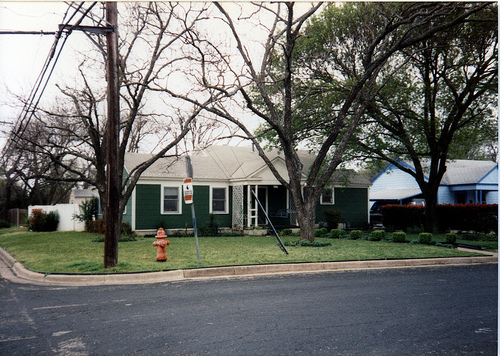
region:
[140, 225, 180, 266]
red fire hydrant on grass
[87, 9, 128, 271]
brown tree trunk on grass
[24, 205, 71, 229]
shrubs in side yard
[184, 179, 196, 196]
white sign on a pole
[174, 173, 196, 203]
white and red sign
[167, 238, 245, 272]
green grass in front lawn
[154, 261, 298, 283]
white curb by street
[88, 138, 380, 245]
A house in the foreground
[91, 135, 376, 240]
The house is green in color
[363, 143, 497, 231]
A white house on the right side of the image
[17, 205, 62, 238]
A bush in the background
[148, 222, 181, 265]
A fire hydrant in the foreground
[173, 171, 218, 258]
A street sign in the foreground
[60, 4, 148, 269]
A wooden pole in the foreground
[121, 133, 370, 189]
The roof of the house is light gray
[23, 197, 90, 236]
A white fence in the background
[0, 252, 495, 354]
A concrete street in the foreground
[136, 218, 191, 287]
this is a fire hydrant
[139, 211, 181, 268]
the hydrant is on the grass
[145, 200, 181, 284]
the hydrant is on the lawn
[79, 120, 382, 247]
this is a green house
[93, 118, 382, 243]
a green one-story house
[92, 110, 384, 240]
a detached single family home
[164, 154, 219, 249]
this is a street sign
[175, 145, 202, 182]
this is the back of a stop sign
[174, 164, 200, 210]
this is a neighborhood watch sign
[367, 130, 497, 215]
this is a blue house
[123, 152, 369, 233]
dark green ranch home with white trim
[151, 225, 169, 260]
a red fire hydrant by the road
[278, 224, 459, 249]
small bushes line the front walk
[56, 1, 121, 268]
a utility pole supports utility lines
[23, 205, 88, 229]
a white privacy fence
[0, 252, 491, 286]
a concrete curb along the road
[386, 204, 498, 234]
bushes that have turned red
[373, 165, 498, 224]
a white neighboring house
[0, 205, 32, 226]
a chain link fence down the road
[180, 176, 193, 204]
a posted Neighborhood Watch sign.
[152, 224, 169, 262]
a red colored fire hydrant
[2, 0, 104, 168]
black colored utility lines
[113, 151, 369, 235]
a green house with white accents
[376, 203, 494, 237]
a roll of red bushes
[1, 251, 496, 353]
a dark gray paved road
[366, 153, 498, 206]
a blue house with a gray shingled roof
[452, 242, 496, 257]
a paved sidewalk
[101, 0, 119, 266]
a brown wooden utility pole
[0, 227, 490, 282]
a front yard covered in grass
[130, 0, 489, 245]
a gray bare tree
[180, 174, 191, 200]
sign is on the pole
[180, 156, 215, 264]
the pole is in the grass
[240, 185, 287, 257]
the pole is leaning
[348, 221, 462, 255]
bushes are lining the driveway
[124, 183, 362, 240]
the house is green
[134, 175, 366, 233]
the house has white trim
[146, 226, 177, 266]
the hydrant is in the grass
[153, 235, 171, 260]
the hydrant is red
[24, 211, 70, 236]
bush is by the fence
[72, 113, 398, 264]
house next to trees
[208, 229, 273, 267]
grass on the ground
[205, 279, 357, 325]
street next to grass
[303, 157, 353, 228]
window on a house